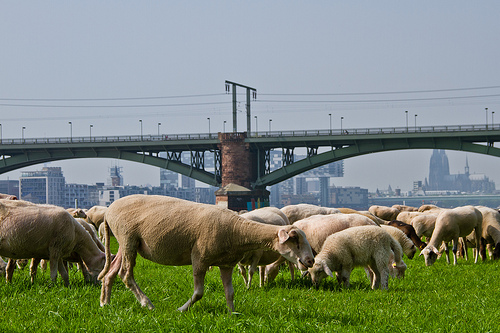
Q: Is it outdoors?
A: Yes, it is outdoors.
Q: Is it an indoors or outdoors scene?
A: It is outdoors.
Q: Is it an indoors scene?
A: No, it is outdoors.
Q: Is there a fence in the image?
A: No, there are no fences.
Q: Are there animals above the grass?
A: Yes, there is an animal above the grass.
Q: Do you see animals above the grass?
A: Yes, there is an animal above the grass.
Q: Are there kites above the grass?
A: No, there is an animal above the grass.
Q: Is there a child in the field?
A: No, there is an animal in the field.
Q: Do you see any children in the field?
A: No, there is an animal in the field.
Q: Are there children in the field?
A: No, there is an animal in the field.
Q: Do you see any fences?
A: No, there are no fences.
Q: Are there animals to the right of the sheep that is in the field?
A: Yes, there is an animal to the right of the sheep.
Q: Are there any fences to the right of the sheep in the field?
A: No, there is an animal to the right of the sheep.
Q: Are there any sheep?
A: Yes, there is a sheep.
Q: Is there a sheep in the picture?
A: Yes, there is a sheep.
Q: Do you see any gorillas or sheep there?
A: Yes, there is a sheep.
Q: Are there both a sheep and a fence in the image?
A: No, there is a sheep but no fences.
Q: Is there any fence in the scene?
A: No, there are no fences.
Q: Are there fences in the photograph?
A: No, there are no fences.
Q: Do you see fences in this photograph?
A: No, there are no fences.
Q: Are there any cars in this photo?
A: No, there are no cars.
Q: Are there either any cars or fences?
A: No, there are no cars or fences.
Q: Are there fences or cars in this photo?
A: No, there are no cars or fences.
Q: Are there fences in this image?
A: No, there are no fences.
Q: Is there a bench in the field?
A: No, there is an animal in the field.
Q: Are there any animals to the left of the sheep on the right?
A: Yes, there is an animal to the left of the sheep.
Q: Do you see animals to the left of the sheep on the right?
A: Yes, there is an animal to the left of the sheep.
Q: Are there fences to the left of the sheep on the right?
A: No, there is an animal to the left of the sheep.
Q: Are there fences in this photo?
A: No, there are no fences.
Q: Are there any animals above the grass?
A: Yes, there is an animal above the grass.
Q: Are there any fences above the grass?
A: No, there is an animal above the grass.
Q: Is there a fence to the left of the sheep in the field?
A: No, there is an animal to the left of the sheep.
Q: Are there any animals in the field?
A: Yes, there is an animal in the field.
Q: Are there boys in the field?
A: No, there is an animal in the field.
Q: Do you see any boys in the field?
A: No, there is an animal in the field.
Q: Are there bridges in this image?
A: Yes, there is a bridge.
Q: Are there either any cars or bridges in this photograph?
A: Yes, there is a bridge.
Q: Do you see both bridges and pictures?
A: No, there is a bridge but no pictures.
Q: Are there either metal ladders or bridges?
A: Yes, there is a metal bridge.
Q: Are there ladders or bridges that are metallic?
A: Yes, the bridge is metallic.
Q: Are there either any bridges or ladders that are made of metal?
A: Yes, the bridge is made of metal.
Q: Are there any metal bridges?
A: Yes, there is a metal bridge.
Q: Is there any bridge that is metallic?
A: Yes, there is a bridge that is metallic.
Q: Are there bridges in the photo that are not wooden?
A: Yes, there is a metallic bridge.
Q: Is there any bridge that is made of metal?
A: Yes, there is a bridge that is made of metal.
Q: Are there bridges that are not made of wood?
A: Yes, there is a bridge that is made of metal.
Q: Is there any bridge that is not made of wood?
A: Yes, there is a bridge that is made of metal.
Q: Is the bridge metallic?
A: Yes, the bridge is metallic.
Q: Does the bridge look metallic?
A: Yes, the bridge is metallic.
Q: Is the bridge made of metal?
A: Yes, the bridge is made of metal.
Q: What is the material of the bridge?
A: The bridge is made of metal.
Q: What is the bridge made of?
A: The bridge is made of metal.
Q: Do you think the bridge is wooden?
A: No, the bridge is metallic.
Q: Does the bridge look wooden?
A: No, the bridge is metallic.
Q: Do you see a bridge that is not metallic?
A: No, there is a bridge but it is metallic.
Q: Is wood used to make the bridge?
A: No, the bridge is made of metal.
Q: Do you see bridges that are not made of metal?
A: No, there is a bridge but it is made of metal.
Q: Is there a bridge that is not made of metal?
A: No, there is a bridge but it is made of metal.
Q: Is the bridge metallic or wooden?
A: The bridge is metallic.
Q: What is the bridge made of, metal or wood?
A: The bridge is made of metal.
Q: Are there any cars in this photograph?
A: No, there are no cars.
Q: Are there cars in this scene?
A: No, there are no cars.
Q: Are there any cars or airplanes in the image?
A: No, there are no cars or airplanes.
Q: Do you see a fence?
A: No, there are no fences.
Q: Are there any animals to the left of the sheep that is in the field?
A: Yes, there is an animal to the left of the sheep.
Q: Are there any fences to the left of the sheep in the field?
A: No, there is an animal to the left of the sheep.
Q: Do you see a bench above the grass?
A: No, there is an animal above the grass.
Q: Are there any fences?
A: No, there are no fences.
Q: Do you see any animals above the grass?
A: Yes, there is an animal above the grass.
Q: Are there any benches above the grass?
A: No, there is an animal above the grass.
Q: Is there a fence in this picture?
A: No, there are no fences.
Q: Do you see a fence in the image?
A: No, there are no fences.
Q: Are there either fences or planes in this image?
A: No, there are no fences or planes.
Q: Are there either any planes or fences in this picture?
A: No, there are no fences or planes.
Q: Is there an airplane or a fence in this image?
A: No, there are no fences or airplanes.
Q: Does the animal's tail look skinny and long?
A: Yes, the tail is skinny and long.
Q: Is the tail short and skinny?
A: No, the tail is skinny but long.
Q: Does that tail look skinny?
A: Yes, the tail is skinny.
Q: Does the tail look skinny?
A: Yes, the tail is skinny.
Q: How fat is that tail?
A: The tail is skinny.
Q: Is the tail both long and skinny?
A: Yes, the tail is long and skinny.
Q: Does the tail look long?
A: Yes, the tail is long.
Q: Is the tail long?
A: Yes, the tail is long.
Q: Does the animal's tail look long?
A: Yes, the tail is long.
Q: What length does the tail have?
A: The tail has long length.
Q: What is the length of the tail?
A: The tail is long.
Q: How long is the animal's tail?
A: The tail is long.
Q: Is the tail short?
A: No, the tail is long.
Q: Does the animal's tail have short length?
A: No, the tail is long.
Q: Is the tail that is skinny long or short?
A: The tail is long.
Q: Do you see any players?
A: No, there are no players.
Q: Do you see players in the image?
A: No, there are no players.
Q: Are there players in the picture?
A: No, there are no players.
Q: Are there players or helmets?
A: No, there are no players or helmets.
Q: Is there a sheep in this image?
A: Yes, there is a sheep.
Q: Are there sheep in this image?
A: Yes, there is a sheep.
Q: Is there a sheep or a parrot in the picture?
A: Yes, there is a sheep.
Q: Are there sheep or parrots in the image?
A: Yes, there is a sheep.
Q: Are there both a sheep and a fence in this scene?
A: No, there is a sheep but no fences.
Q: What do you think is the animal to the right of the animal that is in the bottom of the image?
A: The animal is a sheep.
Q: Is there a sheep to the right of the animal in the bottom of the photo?
A: Yes, there is a sheep to the right of the animal.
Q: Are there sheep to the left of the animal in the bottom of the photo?
A: No, the sheep is to the right of the animal.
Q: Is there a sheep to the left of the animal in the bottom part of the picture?
A: No, the sheep is to the right of the animal.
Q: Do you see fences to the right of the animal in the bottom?
A: No, there is a sheep to the right of the animal.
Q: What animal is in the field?
A: The animal is a sheep.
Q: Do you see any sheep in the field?
A: Yes, there is a sheep in the field.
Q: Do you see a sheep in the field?
A: Yes, there is a sheep in the field.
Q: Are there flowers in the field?
A: No, there is a sheep in the field.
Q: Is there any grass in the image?
A: Yes, there is grass.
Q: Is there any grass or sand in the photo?
A: Yes, there is grass.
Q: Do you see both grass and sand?
A: No, there is grass but no sand.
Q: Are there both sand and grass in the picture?
A: No, there is grass but no sand.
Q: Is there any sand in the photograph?
A: No, there is no sand.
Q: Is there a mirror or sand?
A: No, there are no sand or mirrors.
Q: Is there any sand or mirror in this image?
A: No, there are no sand or mirrors.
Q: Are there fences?
A: No, there are no fences.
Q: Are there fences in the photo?
A: No, there are no fences.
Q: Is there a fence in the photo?
A: No, there are no fences.